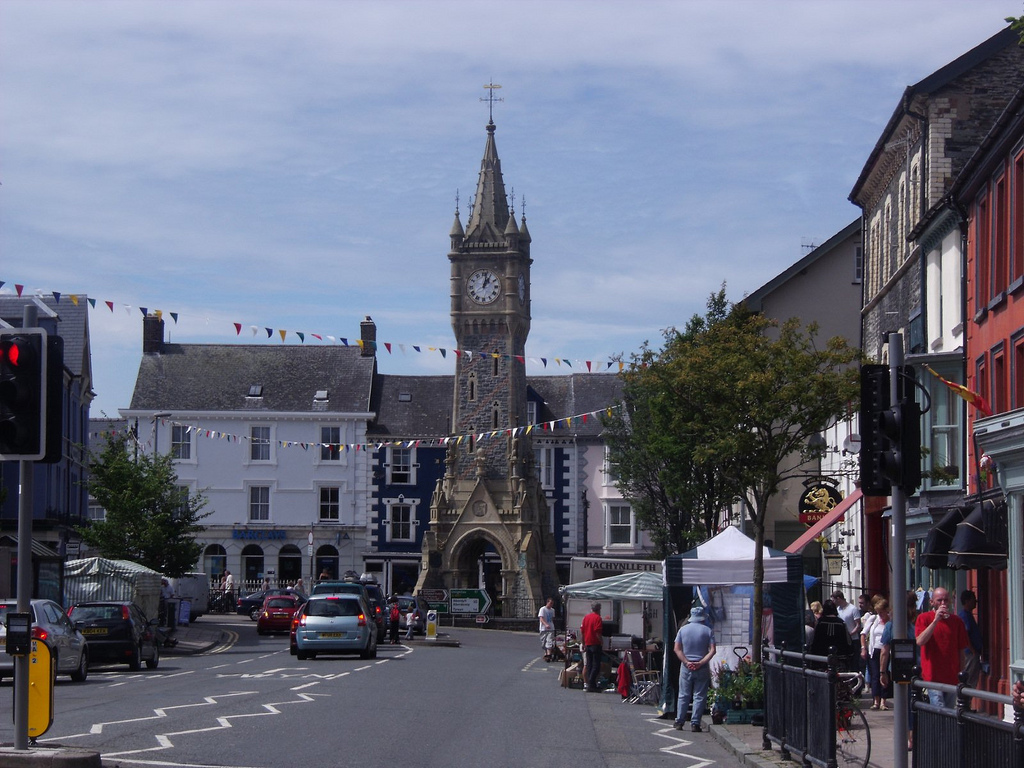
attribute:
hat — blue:
[680, 600, 720, 628]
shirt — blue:
[669, 618, 721, 664]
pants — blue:
[671, 659, 718, 729]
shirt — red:
[577, 597, 606, 646]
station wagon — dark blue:
[68, 589, 172, 679]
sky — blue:
[2, 7, 1012, 384]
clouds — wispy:
[2, 5, 1020, 381]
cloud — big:
[25, 35, 337, 217]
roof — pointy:
[451, 113, 527, 252]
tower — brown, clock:
[393, 111, 590, 641]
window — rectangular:
[244, 415, 277, 474]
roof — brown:
[114, 318, 382, 418]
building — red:
[907, 89, 1020, 766]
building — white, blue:
[365, 376, 573, 629]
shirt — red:
[554, 576, 626, 669]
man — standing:
[675, 601, 717, 738]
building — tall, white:
[133, 329, 464, 625]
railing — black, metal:
[754, 636, 843, 760]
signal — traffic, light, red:
[9, 333, 31, 377]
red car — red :
[250, 571, 328, 638]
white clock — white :
[459, 262, 518, 312]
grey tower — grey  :
[425, 74, 551, 368]